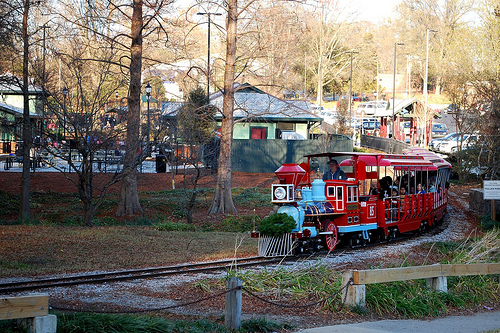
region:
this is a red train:
[267, 110, 469, 298]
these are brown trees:
[131, 32, 245, 219]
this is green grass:
[384, 289, 412, 303]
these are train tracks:
[65, 257, 231, 293]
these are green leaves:
[304, 60, 349, 100]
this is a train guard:
[256, 224, 303, 261]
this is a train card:
[356, 145, 426, 202]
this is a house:
[156, 56, 314, 176]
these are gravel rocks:
[92, 289, 139, 310]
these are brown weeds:
[403, 247, 498, 315]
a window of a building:
[242, 125, 270, 137]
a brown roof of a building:
[167, 79, 315, 121]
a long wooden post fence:
[352, 254, 498, 284]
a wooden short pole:
[225, 276, 244, 331]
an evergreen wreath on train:
[256, 211, 293, 235]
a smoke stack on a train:
[284, 139, 296, 164]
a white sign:
[481, 180, 498, 201]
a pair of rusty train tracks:
[1, 201, 477, 298]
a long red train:
[260, 138, 452, 247]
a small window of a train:
[327, 186, 335, 200]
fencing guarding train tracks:
[5, 257, 495, 328]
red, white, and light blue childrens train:
[253, 136, 449, 261]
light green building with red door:
[189, 79, 317, 143]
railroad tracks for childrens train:
[5, 250, 278, 291]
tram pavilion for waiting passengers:
[375, 96, 436, 146]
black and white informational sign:
[481, 177, 498, 201]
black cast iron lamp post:
[143, 77, 153, 160]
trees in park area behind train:
[5, 1, 243, 230]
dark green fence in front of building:
[208, 135, 353, 169]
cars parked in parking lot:
[312, 102, 466, 149]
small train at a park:
[0, 0, 499, 332]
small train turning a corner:
[254, 144, 455, 259]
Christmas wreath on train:
[253, 209, 297, 241]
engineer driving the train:
[321, 155, 348, 178]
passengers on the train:
[383, 167, 437, 197]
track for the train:
[1, 252, 276, 295]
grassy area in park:
[1, 217, 254, 252]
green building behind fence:
[159, 85, 356, 173]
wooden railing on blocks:
[338, 257, 498, 307]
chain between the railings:
[51, 275, 356, 317]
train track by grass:
[42, 266, 235, 291]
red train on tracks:
[268, 155, 388, 275]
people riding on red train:
[385, 176, 452, 214]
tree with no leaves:
[210, 16, 256, 204]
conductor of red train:
[318, 155, 360, 235]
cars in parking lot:
[411, 106, 471, 152]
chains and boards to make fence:
[220, 272, 448, 319]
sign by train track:
[471, 171, 498, 234]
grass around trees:
[132, 187, 257, 231]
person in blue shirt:
[412, 180, 427, 215]